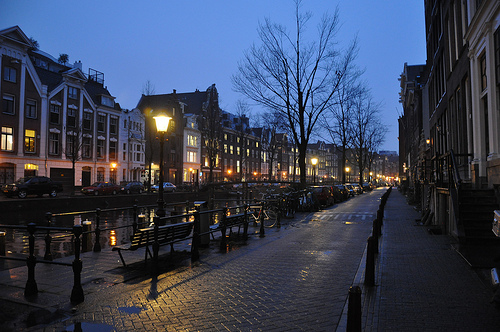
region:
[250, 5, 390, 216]
leave-less trees along road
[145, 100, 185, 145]
lit street lights along road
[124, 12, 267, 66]
dark blue sky above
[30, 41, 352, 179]
row of buildings on left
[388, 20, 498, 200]
row of buildings on right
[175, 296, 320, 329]
bricks laid down on sidewalk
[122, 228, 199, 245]
benches along brick sidewalk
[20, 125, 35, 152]
windows in building across the street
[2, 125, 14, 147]
windows in building across the street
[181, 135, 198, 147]
windows in building across the street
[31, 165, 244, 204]
cars parked on the street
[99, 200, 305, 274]
parks benches next to each other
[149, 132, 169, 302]
black pole to light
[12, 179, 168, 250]
the street is wet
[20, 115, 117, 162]
multiple windows on the building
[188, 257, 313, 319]
brick design on sidewalk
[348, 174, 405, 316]
black poles on sidewalk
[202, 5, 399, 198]
trees without any leafs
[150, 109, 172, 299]
black iron lamp post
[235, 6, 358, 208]
tree with no leaves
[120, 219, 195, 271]
black iron park bench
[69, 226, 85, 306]
iron post in ground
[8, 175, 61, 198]
black truck on street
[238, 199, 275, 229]
yellow bike on sidewalk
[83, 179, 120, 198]
red car on street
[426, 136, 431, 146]
light hanging on porch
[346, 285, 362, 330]
black iron post in ground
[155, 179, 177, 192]
car parked on street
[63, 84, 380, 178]
row of houses by water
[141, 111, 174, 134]
orange light front lamp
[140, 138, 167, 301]
black pole of lamp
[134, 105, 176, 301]
street light by water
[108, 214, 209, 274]
wooden bench on side walk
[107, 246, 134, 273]
black metal frame of bench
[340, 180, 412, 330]
black metal pillars on side walk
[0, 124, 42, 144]
orange window on building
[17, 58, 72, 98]
red roof on building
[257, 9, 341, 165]
tall barren trees on walkway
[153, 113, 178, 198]
lamp with the metal post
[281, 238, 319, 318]
side road with the paved bricks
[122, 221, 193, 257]
black color coated sitting bench in the side walk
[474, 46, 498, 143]
white color frame of the window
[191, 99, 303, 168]
lot of buildings with windows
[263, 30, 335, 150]
tree with branches and leaves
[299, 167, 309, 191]
trunk of the tree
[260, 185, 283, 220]
cycle parked in the parking area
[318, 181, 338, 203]
car parked in the parking area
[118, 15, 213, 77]
a clear blue color sky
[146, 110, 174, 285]
light pole on the street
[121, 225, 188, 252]
bench on the street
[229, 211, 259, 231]
bench on the pavement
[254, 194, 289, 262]
bike parking on the street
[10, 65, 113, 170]
big gray and white building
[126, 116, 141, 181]
white building on the street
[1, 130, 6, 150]
glass window on building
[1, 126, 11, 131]
glass window on building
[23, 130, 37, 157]
glass window on building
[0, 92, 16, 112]
glass window on building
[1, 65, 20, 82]
glass window on building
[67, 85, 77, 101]
glass window on building